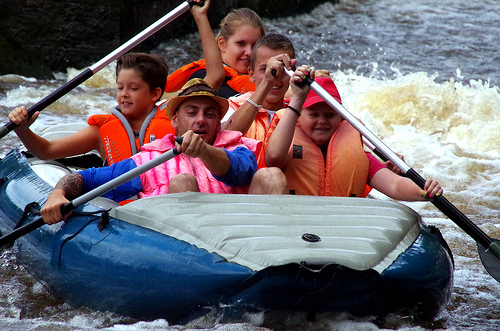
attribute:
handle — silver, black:
[7, 145, 140, 243]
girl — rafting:
[195, 4, 272, 91]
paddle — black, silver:
[305, 72, 498, 277]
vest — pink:
[146, 169, 168, 193]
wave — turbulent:
[403, 61, 465, 153]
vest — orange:
[257, 109, 368, 195]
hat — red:
[298, 75, 340, 108]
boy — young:
[3, 50, 178, 178]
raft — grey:
[112, 158, 414, 288]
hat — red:
[294, 76, 345, 108]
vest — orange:
[269, 119, 370, 200]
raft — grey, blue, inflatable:
[1, 124, 461, 321]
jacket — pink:
[123, 135, 255, 191]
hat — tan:
[165, 77, 230, 121]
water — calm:
[323, 7, 488, 67]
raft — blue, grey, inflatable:
[4, 97, 453, 298]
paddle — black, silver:
[293, 69, 498, 284]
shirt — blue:
[79, 142, 258, 198]